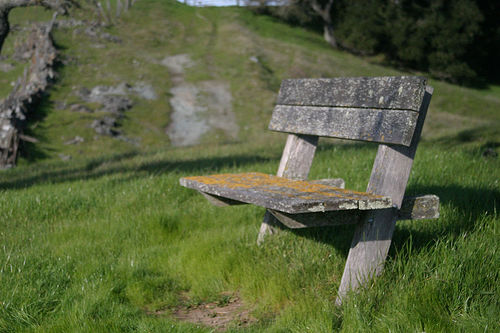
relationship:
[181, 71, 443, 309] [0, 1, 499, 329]
bench in field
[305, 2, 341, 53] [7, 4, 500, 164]
tree in back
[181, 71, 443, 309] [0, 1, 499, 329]
bench on field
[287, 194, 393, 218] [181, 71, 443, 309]
paint scrapings on bench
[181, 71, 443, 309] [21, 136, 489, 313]
bench surrounded by grass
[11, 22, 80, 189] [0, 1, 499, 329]
wall in field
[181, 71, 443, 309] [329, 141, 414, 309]
bench has bar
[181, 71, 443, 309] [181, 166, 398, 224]
bench has seat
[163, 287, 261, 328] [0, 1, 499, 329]
spot in field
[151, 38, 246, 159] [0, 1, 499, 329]
path in field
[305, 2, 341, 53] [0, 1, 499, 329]
tree in field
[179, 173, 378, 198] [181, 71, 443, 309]
moss growing on bench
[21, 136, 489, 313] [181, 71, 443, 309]
grass growing around bench